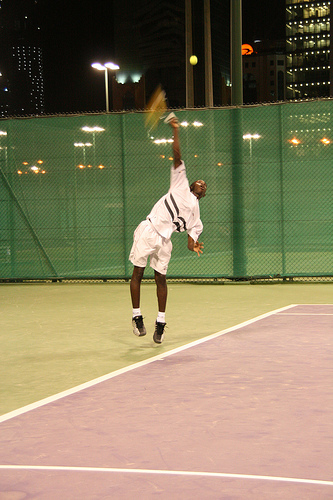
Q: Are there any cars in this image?
A: No, there are no cars.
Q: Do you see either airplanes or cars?
A: No, there are no cars or airplanes.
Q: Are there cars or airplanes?
A: No, there are no cars or airplanes.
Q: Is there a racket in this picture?
A: Yes, there is a racket.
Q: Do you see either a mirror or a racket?
A: Yes, there is a racket.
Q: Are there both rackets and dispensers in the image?
A: No, there is a racket but no dispensers.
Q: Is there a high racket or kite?
A: Yes, there is a high racket.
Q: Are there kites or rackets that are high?
A: Yes, the racket is high.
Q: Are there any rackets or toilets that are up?
A: Yes, the racket is up.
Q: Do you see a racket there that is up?
A: Yes, there is a racket that is up.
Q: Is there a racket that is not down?
A: Yes, there is a racket that is up.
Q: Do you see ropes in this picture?
A: No, there are no ropes.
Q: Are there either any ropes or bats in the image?
A: No, there are no ropes or bats.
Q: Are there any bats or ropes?
A: No, there are no ropes or bats.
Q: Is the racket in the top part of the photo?
A: Yes, the racket is in the top of the image.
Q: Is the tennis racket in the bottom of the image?
A: No, the tennis racket is in the top of the image.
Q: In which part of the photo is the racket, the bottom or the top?
A: The racket is in the top of the image.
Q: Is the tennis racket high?
A: Yes, the tennis racket is high.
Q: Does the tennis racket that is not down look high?
A: Yes, the racket is high.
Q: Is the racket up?
A: Yes, the racket is up.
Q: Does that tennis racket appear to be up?
A: Yes, the tennis racket is up.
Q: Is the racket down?
A: No, the racket is up.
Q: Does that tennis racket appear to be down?
A: No, the tennis racket is up.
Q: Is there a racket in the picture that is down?
A: No, there is a racket but it is up.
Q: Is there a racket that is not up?
A: No, there is a racket but it is up.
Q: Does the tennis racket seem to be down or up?
A: The tennis racket is up.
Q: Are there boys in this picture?
A: No, there are no boys.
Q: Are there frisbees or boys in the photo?
A: No, there are no boys or frisbees.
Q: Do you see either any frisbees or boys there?
A: No, there are no boys or frisbees.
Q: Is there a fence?
A: Yes, there is a fence.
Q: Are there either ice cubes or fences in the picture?
A: Yes, there is a fence.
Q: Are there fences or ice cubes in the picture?
A: Yes, there is a fence.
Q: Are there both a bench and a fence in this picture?
A: No, there is a fence but no benches.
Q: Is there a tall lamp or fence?
A: Yes, there is a tall fence.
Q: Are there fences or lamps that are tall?
A: Yes, the fence is tall.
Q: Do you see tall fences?
A: Yes, there is a tall fence.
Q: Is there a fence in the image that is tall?
A: Yes, there is a fence that is tall.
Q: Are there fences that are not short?
A: Yes, there is a tall fence.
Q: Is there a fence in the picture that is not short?
A: Yes, there is a tall fence.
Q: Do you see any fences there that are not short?
A: Yes, there is a tall fence.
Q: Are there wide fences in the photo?
A: Yes, there is a wide fence.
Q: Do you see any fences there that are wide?
A: Yes, there is a fence that is wide.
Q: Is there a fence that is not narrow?
A: Yes, there is a wide fence.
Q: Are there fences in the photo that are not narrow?
A: Yes, there is a wide fence.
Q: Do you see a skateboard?
A: No, there are no skateboards.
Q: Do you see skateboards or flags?
A: No, there are no skateboards or flags.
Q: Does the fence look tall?
A: Yes, the fence is tall.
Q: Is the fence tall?
A: Yes, the fence is tall.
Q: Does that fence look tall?
A: Yes, the fence is tall.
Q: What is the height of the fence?
A: The fence is tall.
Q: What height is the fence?
A: The fence is tall.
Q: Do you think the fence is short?
A: No, the fence is tall.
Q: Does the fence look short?
A: No, the fence is tall.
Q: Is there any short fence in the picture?
A: No, there is a fence but it is tall.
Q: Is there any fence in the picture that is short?
A: No, there is a fence but it is tall.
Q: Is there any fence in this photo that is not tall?
A: No, there is a fence but it is tall.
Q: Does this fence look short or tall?
A: The fence is tall.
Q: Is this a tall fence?
A: Yes, this is a tall fence.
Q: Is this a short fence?
A: No, this is a tall fence.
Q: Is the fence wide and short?
A: No, the fence is wide but tall.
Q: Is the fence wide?
A: Yes, the fence is wide.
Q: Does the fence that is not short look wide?
A: Yes, the fence is wide.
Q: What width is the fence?
A: The fence is wide.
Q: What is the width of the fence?
A: The fence is wide.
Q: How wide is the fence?
A: The fence is wide.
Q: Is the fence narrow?
A: No, the fence is wide.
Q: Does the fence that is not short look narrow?
A: No, the fence is wide.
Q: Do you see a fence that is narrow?
A: No, there is a fence but it is wide.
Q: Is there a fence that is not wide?
A: No, there is a fence but it is wide.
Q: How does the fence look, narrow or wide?
A: The fence is wide.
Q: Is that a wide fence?
A: Yes, that is a wide fence.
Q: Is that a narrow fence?
A: No, that is a wide fence.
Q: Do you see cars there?
A: No, there are no cars.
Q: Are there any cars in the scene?
A: No, there are no cars.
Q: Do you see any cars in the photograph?
A: No, there are no cars.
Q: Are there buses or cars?
A: No, there are no cars or buses.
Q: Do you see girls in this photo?
A: No, there are no girls.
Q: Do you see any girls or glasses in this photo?
A: No, there are no girls or glasses.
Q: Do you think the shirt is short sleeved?
A: Yes, the shirt is short sleeved.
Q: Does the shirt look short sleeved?
A: Yes, the shirt is short sleeved.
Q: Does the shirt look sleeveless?
A: No, the shirt is short sleeved.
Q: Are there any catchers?
A: No, there are no catchers.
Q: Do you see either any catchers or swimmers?
A: No, there are no catchers or swimmers.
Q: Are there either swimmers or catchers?
A: No, there are no catchers or swimmers.